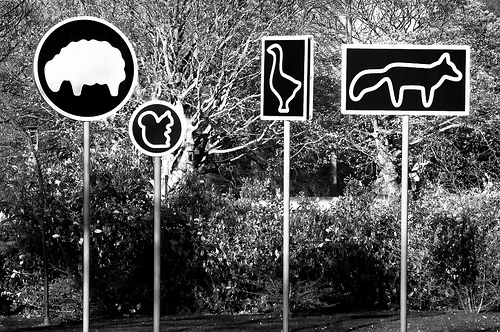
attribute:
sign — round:
[125, 97, 189, 162]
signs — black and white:
[30, 14, 470, 158]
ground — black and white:
[343, 190, 382, 245]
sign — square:
[327, 28, 496, 131]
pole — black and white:
[148, 154, 173, 325]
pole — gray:
[144, 158, 169, 331]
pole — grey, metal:
[79, 120, 94, 330]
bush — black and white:
[213, 197, 348, 304]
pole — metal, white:
[283, 119, 289, 330]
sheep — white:
[31, 36, 133, 101]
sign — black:
[126, 92, 195, 162]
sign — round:
[131, 92, 192, 165]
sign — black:
[309, 30, 483, 127]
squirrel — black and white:
[126, 101, 200, 168]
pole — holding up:
[111, 184, 191, 291]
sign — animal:
[337, 34, 474, 122]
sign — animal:
[252, 31, 310, 129]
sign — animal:
[27, 11, 137, 126]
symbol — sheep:
[331, 37, 456, 130]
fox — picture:
[336, 35, 473, 117]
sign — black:
[258, 34, 316, 122]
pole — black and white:
[393, 122, 413, 330]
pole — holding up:
[395, 112, 419, 329]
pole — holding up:
[278, 114, 293, 330]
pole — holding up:
[145, 155, 165, 330]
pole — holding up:
[82, 116, 92, 330]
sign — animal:
[127, 99, 189, 159]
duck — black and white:
[258, 35, 305, 117]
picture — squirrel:
[127, 97, 184, 152]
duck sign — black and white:
[260, 34, 317, 124]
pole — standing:
[74, 122, 105, 324]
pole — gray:
[59, 131, 184, 329]